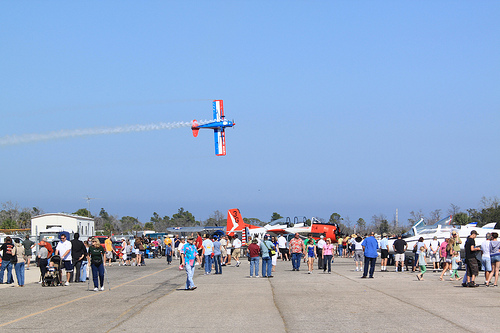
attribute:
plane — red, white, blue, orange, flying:
[188, 98, 237, 158]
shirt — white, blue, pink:
[180, 243, 200, 268]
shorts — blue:
[59, 259, 75, 274]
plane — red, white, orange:
[224, 206, 340, 239]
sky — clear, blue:
[1, 1, 499, 155]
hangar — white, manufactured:
[29, 211, 96, 243]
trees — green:
[91, 209, 222, 231]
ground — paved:
[1, 286, 498, 330]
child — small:
[46, 259, 57, 276]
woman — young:
[306, 239, 319, 271]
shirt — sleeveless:
[305, 245, 315, 258]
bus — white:
[38, 227, 74, 249]